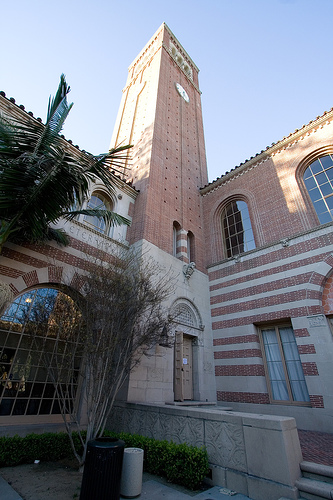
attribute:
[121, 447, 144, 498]
ash tray — white, cement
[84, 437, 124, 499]
trash can — round, black, metal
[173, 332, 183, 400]
door — open, light brown, panel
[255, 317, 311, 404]
window — paneled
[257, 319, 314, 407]
trim — brown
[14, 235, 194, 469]
tree — leafless, skinny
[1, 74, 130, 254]
palm tree — green, bright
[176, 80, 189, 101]
clock — white, round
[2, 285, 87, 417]
window — large, arched, long, big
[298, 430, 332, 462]
sidewalk — red, brick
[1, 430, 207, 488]
hedge row — bright green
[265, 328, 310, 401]
curtain — white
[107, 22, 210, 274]
tower — pink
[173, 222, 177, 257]
window — small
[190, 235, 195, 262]
window — small